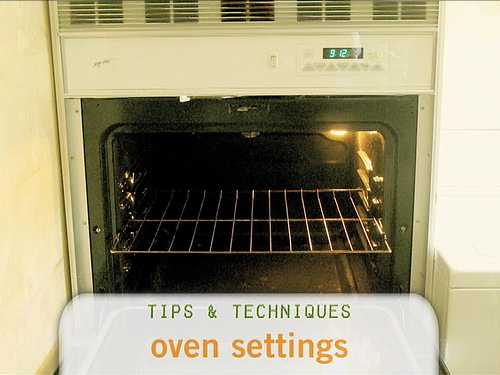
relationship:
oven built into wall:
[50, 27, 437, 338] [448, 37, 495, 254]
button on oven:
[299, 62, 315, 74] [50, 7, 412, 373]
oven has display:
[46, 1, 448, 293] [318, 44, 366, 63]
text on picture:
[147, 303, 351, 363] [0, 1, 499, 371]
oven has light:
[46, 1, 448, 293] [235, 128, 262, 145]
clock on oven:
[322, 46, 363, 58] [46, 1, 448, 293]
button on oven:
[340, 60, 352, 72] [50, 7, 412, 373]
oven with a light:
[46, 1, 448, 293] [323, 127, 353, 142]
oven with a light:
[46, 1, 448, 293] [326, 126, 347, 136]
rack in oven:
[226, 198, 348, 252] [46, 1, 448, 293]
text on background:
[147, 303, 351, 363] [58, 288, 443, 373]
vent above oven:
[56, 0, 433, 24] [46, 1, 448, 293]